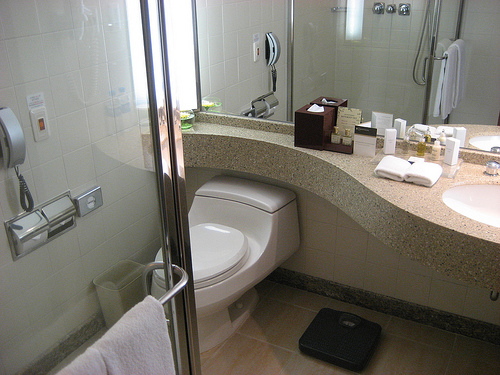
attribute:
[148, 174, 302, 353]
toilet — porcelain, white, folded, closed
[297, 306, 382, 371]
scale — black, analog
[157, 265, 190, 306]
towel rack — silver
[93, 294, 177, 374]
towel — folded, white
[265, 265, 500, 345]
base board — gray, white, black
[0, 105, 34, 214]
telephone — silver, corded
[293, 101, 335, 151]
tissue box — brown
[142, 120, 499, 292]
counter — speckled, beige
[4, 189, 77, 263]
toilet paper holder — silver, built in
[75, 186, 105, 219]
tissue holder — silver, built in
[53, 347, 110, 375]
towel — white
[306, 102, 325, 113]
tissue — white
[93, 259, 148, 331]
trashcan — empty, white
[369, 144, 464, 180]
plate — glass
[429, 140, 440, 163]
hair product — travel size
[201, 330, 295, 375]
tile — pink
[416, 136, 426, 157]
bottle — yellow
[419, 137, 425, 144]
top — white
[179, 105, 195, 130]
bowl — glass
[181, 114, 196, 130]
liquid — green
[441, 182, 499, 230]
sink — built in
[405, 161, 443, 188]
towel — white, folded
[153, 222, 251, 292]
toilet bowl — white